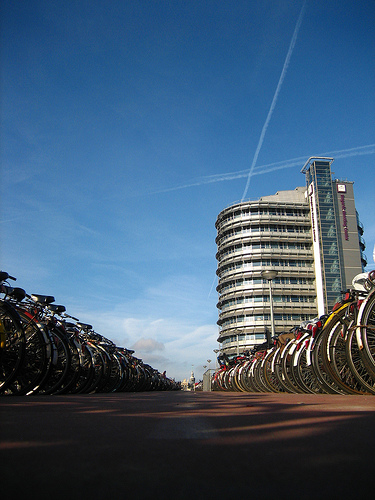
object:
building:
[214, 156, 369, 361]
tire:
[212, 289, 375, 396]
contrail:
[239, 1, 308, 203]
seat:
[31, 294, 55, 307]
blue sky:
[0, 0, 375, 384]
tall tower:
[190, 371, 196, 385]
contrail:
[141, 142, 375, 199]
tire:
[0, 303, 182, 399]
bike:
[0, 271, 182, 399]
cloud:
[0, 0, 375, 385]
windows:
[214, 207, 310, 226]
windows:
[213, 258, 318, 276]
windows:
[215, 223, 312, 246]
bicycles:
[211, 268, 375, 396]